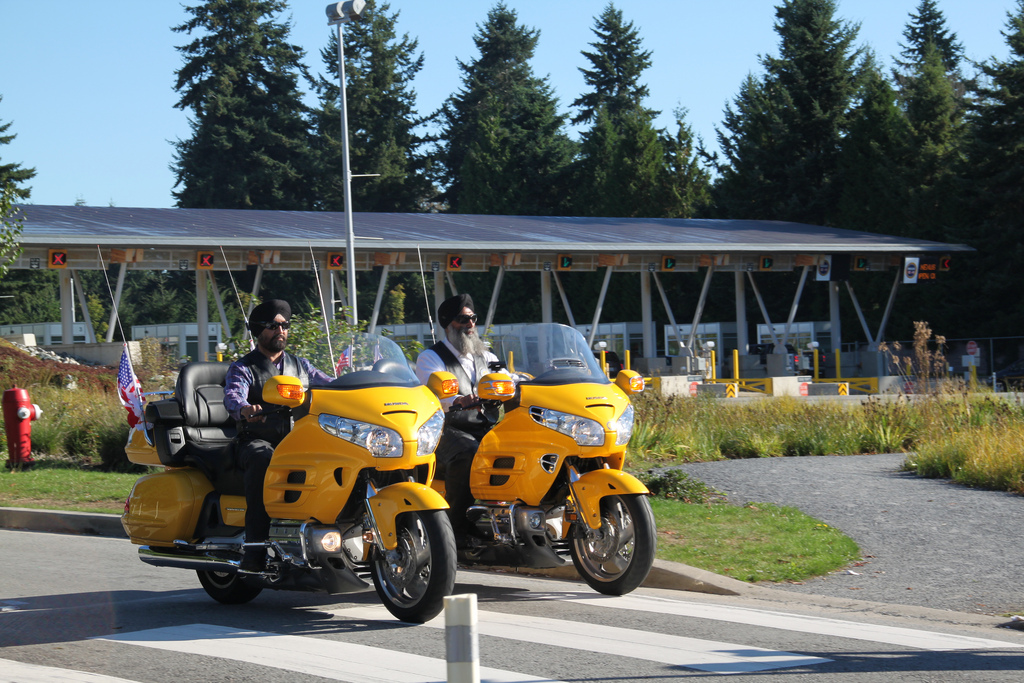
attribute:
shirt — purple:
[218, 349, 327, 439]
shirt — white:
[419, 333, 509, 419]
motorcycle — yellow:
[127, 351, 469, 637]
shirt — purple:
[224, 345, 348, 421]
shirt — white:
[410, 342, 521, 425]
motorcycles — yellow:
[125, 283, 660, 625]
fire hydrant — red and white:
[0, 377, 48, 470]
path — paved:
[676, 443, 1022, 618]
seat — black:
[161, 358, 238, 460]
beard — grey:
[443, 321, 486, 357]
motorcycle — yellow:
[430, 320, 665, 597]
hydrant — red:
[2, 383, 48, 473]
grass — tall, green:
[653, 392, 1018, 602]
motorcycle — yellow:
[119, 329, 462, 624]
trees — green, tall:
[157, 0, 1020, 283]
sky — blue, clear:
[19, 0, 1016, 124]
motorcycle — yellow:
[125, 299, 446, 625]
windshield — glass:
[476, 321, 598, 372]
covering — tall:
[0, 215, 931, 291]